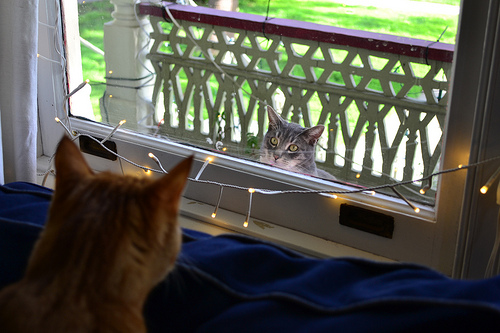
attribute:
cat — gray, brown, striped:
[254, 104, 329, 178]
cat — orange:
[3, 128, 197, 332]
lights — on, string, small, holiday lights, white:
[45, 83, 494, 212]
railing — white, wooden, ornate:
[102, 5, 461, 197]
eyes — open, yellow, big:
[267, 131, 303, 154]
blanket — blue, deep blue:
[3, 184, 497, 332]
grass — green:
[231, 2, 461, 45]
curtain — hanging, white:
[1, 2, 40, 187]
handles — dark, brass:
[80, 137, 398, 240]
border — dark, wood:
[163, 8, 458, 60]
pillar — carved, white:
[101, 2, 161, 132]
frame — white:
[38, 7, 477, 244]